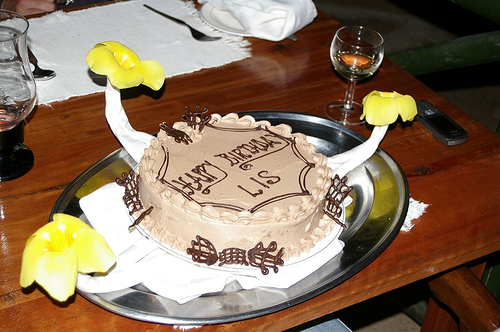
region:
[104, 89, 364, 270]
a chocolate frosted cake.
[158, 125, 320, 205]
chocolate writing on a chocolate cake.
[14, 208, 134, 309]
flowers on a chocolate cake.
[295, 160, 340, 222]
chocolate frosting ribbon.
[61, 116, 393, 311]
white paper under a cake.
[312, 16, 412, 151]
a glass on top of a table.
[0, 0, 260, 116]
a blanket on a table.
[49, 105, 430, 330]
a metal pan under a cake.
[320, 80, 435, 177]
a yellow flower on a white object.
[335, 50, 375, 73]
A liquid in a glass.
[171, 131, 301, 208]
black lettering on a cake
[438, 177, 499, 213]
brown wooden surface of the table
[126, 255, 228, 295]
white cloth under the cake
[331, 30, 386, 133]
a wine glass on the table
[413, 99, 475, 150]
grey cell phone on the table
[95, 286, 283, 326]
a shiny silver platter on the table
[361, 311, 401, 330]
grey carpet of the room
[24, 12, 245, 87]
a white cloth placemat on the table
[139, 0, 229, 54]
a metal fork on the placemat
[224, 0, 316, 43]
a balled up cloth napkin on a plate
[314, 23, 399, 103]
glass next to cake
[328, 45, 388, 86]
liquid in the glass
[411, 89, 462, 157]
phone on the table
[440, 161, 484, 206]
table under the cake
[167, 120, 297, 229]
frosting on the cake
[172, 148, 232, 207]
word on the cake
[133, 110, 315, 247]
dark frosting on the cake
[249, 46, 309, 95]
reflection on the table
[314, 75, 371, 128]
bottom of the glass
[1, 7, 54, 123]
glass near the cake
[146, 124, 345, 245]
a cake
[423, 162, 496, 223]
a brown table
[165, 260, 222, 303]
a white napkin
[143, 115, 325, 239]
a chocolate cake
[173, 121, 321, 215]
writing on the cake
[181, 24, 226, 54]
a fork on the place mat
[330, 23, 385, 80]
a glass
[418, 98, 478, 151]
a cellphone on the table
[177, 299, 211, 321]
a silver platter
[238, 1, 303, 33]
a white napkin on a plate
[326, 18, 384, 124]
Wine glass on table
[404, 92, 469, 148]
Gray cellphone on table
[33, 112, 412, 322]
Silver platter on table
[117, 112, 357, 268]
Circular cake on platter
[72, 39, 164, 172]
Yellow flower on platter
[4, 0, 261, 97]
White place mat on table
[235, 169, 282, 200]
Brown letters on cake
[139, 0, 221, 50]
Fork on place mat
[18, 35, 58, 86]
Spoon on place mat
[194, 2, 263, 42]
White plate on table